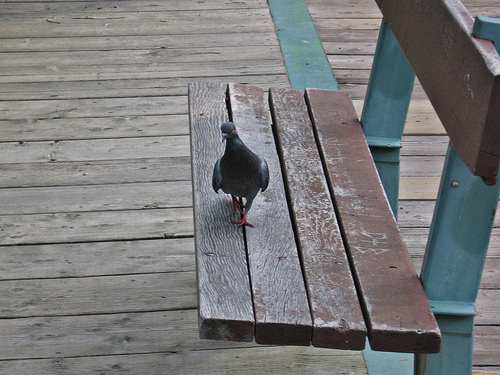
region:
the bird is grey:
[201, 113, 303, 259]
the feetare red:
[221, 200, 255, 233]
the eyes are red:
[226, 121, 236, 135]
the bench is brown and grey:
[199, 232, 411, 334]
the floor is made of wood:
[34, 145, 132, 370]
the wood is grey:
[56, 192, 134, 311]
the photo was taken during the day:
[3, 26, 499, 353]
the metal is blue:
[421, 182, 491, 297]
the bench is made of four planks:
[193, 69, 433, 352]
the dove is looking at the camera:
[198, 123, 293, 247]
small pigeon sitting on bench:
[188, 112, 280, 243]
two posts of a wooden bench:
[200, 243, 314, 331]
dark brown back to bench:
[304, 203, 394, 348]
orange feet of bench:
[220, 197, 265, 232]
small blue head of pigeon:
[211, 122, 243, 143]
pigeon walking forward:
[194, 111, 271, 245]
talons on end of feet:
[231, 217, 259, 229]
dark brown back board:
[415, 3, 485, 182]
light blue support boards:
[424, 180, 480, 313]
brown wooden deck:
[0, 75, 147, 327]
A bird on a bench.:
[210, 122, 270, 229]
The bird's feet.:
[231, 197, 251, 226]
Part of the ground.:
[63, 200, 138, 273]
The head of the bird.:
[218, 120, 238, 143]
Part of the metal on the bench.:
[378, 65, 400, 122]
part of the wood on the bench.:
[316, 260, 353, 324]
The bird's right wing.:
[259, 159, 269, 192]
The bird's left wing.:
[213, 159, 223, 194]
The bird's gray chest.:
[224, 183, 258, 195]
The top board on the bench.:
[378, 0, 499, 185]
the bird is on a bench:
[197, 108, 301, 242]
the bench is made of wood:
[187, 240, 325, 330]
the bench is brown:
[192, 275, 272, 322]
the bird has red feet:
[217, 198, 282, 236]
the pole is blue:
[408, 204, 484, 298]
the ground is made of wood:
[62, 225, 172, 350]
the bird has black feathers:
[220, 143, 274, 198]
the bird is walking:
[217, 115, 321, 267]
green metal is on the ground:
[267, 15, 359, 75]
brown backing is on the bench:
[412, 13, 487, 95]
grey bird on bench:
[211, 121, 269, 226]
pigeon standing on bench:
[213, 120, 270, 228]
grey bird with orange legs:
[212, 121, 267, 229]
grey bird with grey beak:
[212, 118, 269, 220]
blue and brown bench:
[188, 2, 498, 373]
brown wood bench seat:
[188, 80, 443, 353]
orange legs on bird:
[227, 194, 252, 232]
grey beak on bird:
[218, 133, 228, 143]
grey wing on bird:
[261, 158, 269, 193]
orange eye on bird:
[229, 126, 234, 133]